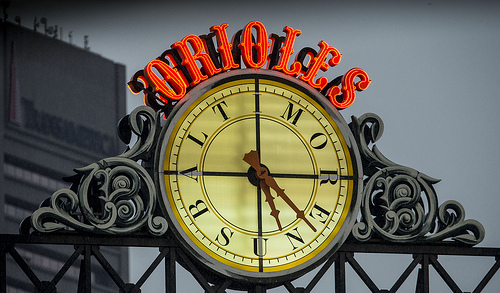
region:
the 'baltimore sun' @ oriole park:
[16, 12, 489, 283]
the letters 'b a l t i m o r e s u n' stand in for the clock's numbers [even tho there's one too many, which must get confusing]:
[175, 85, 342, 255]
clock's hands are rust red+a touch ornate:
[241, 145, 322, 240]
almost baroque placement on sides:
[15, 102, 486, 263]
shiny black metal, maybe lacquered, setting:
[16, 71, 491, 286]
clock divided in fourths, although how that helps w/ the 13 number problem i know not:
[175, 80, 357, 271]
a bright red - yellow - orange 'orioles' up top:
[119, 20, 375, 114]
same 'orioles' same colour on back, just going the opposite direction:
[104, 11, 356, 117]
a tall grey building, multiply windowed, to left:
[0, 11, 136, 289]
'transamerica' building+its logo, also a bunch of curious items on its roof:
[3, 10, 127, 167]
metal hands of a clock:
[243, 145, 318, 238]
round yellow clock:
[165, 73, 349, 267]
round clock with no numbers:
[165, 70, 349, 269]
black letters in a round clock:
[175, 85, 340, 262]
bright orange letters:
[138, 22, 369, 114]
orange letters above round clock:
[142, 21, 372, 119]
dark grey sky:
[378, 10, 495, 101]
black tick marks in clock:
[256, 83, 351, 178]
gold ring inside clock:
[160, 73, 350, 270]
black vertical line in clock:
[245, 81, 277, 278]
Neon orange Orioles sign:
[128, 17, 368, 123]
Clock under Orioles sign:
[148, 65, 368, 280]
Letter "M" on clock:
[275, 102, 305, 127]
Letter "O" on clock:
[306, 126, 331, 155]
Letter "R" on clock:
[315, 165, 342, 190]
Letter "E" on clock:
[303, 202, 333, 226]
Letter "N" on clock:
[277, 227, 307, 250]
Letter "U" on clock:
[250, 236, 272, 258]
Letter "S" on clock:
[212, 222, 237, 245]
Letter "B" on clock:
[186, 192, 210, 224]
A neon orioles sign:
[131, 18, 370, 110]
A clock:
[153, 65, 363, 285]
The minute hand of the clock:
[244, 151, 315, 230]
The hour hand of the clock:
[259, 178, 282, 231]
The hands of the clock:
[242, 150, 319, 234]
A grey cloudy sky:
[13, 5, 498, 291]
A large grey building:
[5, 18, 130, 292]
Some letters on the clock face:
[177, 92, 341, 259]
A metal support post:
[6, 233, 498, 290]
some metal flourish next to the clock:
[349, 108, 486, 248]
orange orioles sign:
[128, 18, 372, 118]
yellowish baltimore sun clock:
[150, 66, 364, 280]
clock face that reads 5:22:
[145, 65, 372, 285]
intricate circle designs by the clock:
[21, 105, 487, 246]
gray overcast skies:
[125, 7, 498, 291]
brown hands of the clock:
[241, 146, 318, 234]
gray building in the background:
[1, 7, 131, 291]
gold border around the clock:
[160, 77, 355, 273]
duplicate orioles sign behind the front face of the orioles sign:
[128, 28, 354, 120]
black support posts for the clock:
[1, 230, 499, 292]